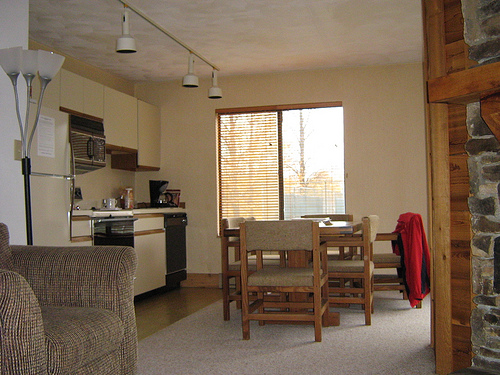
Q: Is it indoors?
A: Yes, it is indoors.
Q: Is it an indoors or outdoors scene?
A: It is indoors.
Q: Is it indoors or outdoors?
A: It is indoors.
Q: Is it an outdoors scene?
A: No, it is indoors.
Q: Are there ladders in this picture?
A: No, there are no ladders.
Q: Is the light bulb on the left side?
A: Yes, the light bulb is on the left of the image.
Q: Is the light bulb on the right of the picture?
A: No, the light bulb is on the left of the image.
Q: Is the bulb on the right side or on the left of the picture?
A: The bulb is on the left of the image.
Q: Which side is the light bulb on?
A: The light bulb is on the left of the image.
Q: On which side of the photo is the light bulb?
A: The light bulb is on the left of the image.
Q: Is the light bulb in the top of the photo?
A: Yes, the light bulb is in the top of the image.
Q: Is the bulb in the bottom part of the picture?
A: No, the bulb is in the top of the image.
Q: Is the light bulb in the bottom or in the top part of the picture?
A: The light bulb is in the top of the image.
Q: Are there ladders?
A: No, there are no ladders.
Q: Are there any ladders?
A: No, there are no ladders.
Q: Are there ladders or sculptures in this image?
A: No, there are no ladders or sculptures.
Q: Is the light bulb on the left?
A: Yes, the light bulb is on the left of the image.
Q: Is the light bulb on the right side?
A: No, the light bulb is on the left of the image.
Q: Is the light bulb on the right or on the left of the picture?
A: The light bulb is on the left of the image.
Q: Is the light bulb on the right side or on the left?
A: The light bulb is on the left of the image.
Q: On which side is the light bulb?
A: The light bulb is on the left of the image.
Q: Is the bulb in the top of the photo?
A: Yes, the bulb is in the top of the image.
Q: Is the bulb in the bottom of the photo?
A: No, the bulb is in the top of the image.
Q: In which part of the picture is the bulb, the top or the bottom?
A: The bulb is in the top of the image.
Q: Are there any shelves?
A: No, there are no shelves.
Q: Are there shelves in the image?
A: No, there are no shelves.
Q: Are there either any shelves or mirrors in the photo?
A: No, there are no shelves or mirrors.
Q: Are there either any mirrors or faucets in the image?
A: No, there are no faucets or mirrors.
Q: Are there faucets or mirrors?
A: No, there are no faucets or mirrors.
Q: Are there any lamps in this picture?
A: Yes, there is a lamp.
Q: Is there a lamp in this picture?
A: Yes, there is a lamp.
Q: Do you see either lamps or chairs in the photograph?
A: Yes, there is a lamp.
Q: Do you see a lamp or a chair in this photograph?
A: Yes, there is a lamp.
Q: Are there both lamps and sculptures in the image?
A: No, there is a lamp but no sculptures.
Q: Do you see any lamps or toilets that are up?
A: Yes, the lamp is up.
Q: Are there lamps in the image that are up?
A: Yes, there is a lamp that is up.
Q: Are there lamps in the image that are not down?
A: Yes, there is a lamp that is up.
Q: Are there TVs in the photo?
A: No, there are no tvs.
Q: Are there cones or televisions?
A: No, there are no televisions or cones.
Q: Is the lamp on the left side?
A: Yes, the lamp is on the left of the image.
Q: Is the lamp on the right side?
A: No, the lamp is on the left of the image.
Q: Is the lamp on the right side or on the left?
A: The lamp is on the left of the image.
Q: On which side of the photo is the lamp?
A: The lamp is on the left of the image.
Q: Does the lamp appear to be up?
A: Yes, the lamp is up.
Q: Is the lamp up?
A: Yes, the lamp is up.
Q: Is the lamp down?
A: No, the lamp is up.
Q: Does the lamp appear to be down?
A: No, the lamp is up.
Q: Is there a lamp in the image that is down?
A: No, there is a lamp but it is up.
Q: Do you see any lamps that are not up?
A: No, there is a lamp but it is up.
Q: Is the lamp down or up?
A: The lamp is up.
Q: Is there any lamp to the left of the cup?
A: Yes, there is a lamp to the left of the cup.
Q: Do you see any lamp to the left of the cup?
A: Yes, there is a lamp to the left of the cup.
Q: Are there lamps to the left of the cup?
A: Yes, there is a lamp to the left of the cup.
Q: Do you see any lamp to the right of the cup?
A: No, the lamp is to the left of the cup.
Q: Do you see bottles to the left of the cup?
A: No, there is a lamp to the left of the cup.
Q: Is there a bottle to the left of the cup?
A: No, there is a lamp to the left of the cup.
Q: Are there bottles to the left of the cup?
A: No, there is a lamp to the left of the cup.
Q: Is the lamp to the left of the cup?
A: Yes, the lamp is to the left of the cup.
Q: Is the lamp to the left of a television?
A: No, the lamp is to the left of the cup.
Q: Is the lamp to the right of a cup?
A: No, the lamp is to the left of a cup.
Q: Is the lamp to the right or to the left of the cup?
A: The lamp is to the left of the cup.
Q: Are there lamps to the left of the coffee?
A: Yes, there is a lamp to the left of the coffee.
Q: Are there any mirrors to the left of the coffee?
A: No, there is a lamp to the left of the coffee.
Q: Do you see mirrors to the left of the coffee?
A: No, there is a lamp to the left of the coffee.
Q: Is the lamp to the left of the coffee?
A: Yes, the lamp is to the left of the coffee.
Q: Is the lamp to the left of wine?
A: No, the lamp is to the left of the coffee.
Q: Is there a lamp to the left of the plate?
A: Yes, there is a lamp to the left of the plate.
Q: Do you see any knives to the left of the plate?
A: No, there is a lamp to the left of the plate.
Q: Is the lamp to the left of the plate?
A: Yes, the lamp is to the left of the plate.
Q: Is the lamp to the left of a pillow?
A: No, the lamp is to the left of the plate.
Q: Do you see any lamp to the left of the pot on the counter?
A: Yes, there is a lamp to the left of the pot.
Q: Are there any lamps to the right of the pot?
A: No, the lamp is to the left of the pot.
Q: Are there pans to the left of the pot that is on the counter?
A: No, there is a lamp to the left of the pot.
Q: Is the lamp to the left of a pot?
A: Yes, the lamp is to the left of a pot.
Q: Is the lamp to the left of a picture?
A: No, the lamp is to the left of a pot.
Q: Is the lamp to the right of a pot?
A: No, the lamp is to the left of a pot.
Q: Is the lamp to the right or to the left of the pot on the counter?
A: The lamp is to the left of the pot.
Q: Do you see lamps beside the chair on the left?
A: Yes, there is a lamp beside the chair.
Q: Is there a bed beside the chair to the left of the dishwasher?
A: No, there is a lamp beside the chair.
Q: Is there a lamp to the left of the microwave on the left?
A: Yes, there is a lamp to the left of the microwave.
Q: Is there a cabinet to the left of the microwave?
A: No, there is a lamp to the left of the microwave.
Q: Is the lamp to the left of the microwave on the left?
A: Yes, the lamp is to the left of the microwave.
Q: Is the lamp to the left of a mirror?
A: No, the lamp is to the left of the microwave.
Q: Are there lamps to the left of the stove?
A: Yes, there is a lamp to the left of the stove.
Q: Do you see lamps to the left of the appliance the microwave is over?
A: Yes, there is a lamp to the left of the stove.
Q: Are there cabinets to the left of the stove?
A: No, there is a lamp to the left of the stove.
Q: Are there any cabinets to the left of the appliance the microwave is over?
A: No, there is a lamp to the left of the stove.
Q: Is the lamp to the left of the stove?
A: Yes, the lamp is to the left of the stove.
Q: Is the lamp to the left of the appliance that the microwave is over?
A: Yes, the lamp is to the left of the stove.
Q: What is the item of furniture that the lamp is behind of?
A: The piece of furniture is a chair.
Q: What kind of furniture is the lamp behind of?
A: The lamp is behind the chair.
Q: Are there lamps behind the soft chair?
A: Yes, there is a lamp behind the chair.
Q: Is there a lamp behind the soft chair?
A: Yes, there is a lamp behind the chair.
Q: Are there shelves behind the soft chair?
A: No, there is a lamp behind the chair.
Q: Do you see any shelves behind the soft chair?
A: No, there is a lamp behind the chair.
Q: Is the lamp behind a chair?
A: Yes, the lamp is behind a chair.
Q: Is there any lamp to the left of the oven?
A: Yes, there is a lamp to the left of the oven.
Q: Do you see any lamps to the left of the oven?
A: Yes, there is a lamp to the left of the oven.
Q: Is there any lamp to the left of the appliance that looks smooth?
A: Yes, there is a lamp to the left of the oven.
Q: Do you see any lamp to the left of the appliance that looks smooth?
A: Yes, there is a lamp to the left of the oven.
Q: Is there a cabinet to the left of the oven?
A: No, there is a lamp to the left of the oven.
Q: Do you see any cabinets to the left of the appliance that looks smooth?
A: No, there is a lamp to the left of the oven.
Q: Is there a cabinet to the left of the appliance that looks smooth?
A: No, there is a lamp to the left of the oven.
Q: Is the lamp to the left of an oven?
A: Yes, the lamp is to the left of an oven.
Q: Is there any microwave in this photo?
A: Yes, there is a microwave.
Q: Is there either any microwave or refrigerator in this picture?
A: Yes, there is a microwave.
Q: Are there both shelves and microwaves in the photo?
A: No, there is a microwave but no shelves.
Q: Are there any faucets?
A: No, there are no faucets.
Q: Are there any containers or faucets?
A: No, there are no faucets or containers.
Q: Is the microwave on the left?
A: Yes, the microwave is on the left of the image.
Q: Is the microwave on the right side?
A: No, the microwave is on the left of the image.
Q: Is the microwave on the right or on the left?
A: The microwave is on the left of the image.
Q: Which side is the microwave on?
A: The microwave is on the left of the image.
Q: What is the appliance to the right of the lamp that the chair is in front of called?
A: The appliance is a microwave.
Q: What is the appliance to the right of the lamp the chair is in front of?
A: The appliance is a microwave.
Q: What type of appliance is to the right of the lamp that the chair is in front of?
A: The appliance is a microwave.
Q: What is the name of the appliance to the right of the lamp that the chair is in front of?
A: The appliance is a microwave.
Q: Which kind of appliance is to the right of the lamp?
A: The appliance is a microwave.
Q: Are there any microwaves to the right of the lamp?
A: Yes, there is a microwave to the right of the lamp.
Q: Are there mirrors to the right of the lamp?
A: No, there is a microwave to the right of the lamp.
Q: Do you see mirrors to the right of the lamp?
A: No, there is a microwave to the right of the lamp.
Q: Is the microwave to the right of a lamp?
A: Yes, the microwave is to the right of a lamp.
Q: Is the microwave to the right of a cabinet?
A: No, the microwave is to the right of a lamp.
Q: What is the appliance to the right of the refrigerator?
A: The appliance is a microwave.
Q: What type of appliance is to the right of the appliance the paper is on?
A: The appliance is a microwave.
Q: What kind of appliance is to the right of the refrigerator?
A: The appliance is a microwave.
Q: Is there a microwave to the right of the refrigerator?
A: Yes, there is a microwave to the right of the refrigerator.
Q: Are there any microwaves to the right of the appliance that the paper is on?
A: Yes, there is a microwave to the right of the refrigerator.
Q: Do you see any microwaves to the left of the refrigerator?
A: No, the microwave is to the right of the refrigerator.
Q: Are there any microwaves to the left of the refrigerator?
A: No, the microwave is to the right of the refrigerator.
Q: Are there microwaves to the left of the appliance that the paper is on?
A: No, the microwave is to the right of the refrigerator.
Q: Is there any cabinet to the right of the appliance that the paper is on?
A: No, there is a microwave to the right of the refrigerator.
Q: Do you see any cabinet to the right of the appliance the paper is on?
A: No, there is a microwave to the right of the refrigerator.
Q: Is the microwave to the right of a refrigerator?
A: Yes, the microwave is to the right of a refrigerator.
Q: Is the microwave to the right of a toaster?
A: No, the microwave is to the right of a refrigerator.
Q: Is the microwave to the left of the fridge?
A: No, the microwave is to the right of the fridge.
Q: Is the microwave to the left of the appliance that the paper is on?
A: No, the microwave is to the right of the fridge.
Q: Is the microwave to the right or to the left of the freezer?
A: The microwave is to the right of the freezer.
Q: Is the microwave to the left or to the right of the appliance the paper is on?
A: The microwave is to the right of the freezer.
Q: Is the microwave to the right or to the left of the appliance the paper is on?
A: The microwave is to the right of the freezer.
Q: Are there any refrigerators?
A: Yes, there is a refrigerator.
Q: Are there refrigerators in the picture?
A: Yes, there is a refrigerator.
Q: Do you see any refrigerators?
A: Yes, there is a refrigerator.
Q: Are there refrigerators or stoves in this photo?
A: Yes, there is a refrigerator.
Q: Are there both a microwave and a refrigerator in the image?
A: Yes, there are both a refrigerator and a microwave.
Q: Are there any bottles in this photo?
A: No, there are no bottles.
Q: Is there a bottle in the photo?
A: No, there are no bottles.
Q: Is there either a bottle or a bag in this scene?
A: No, there are no bottles or bags.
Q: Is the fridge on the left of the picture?
A: Yes, the fridge is on the left of the image.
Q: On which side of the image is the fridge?
A: The fridge is on the left of the image.